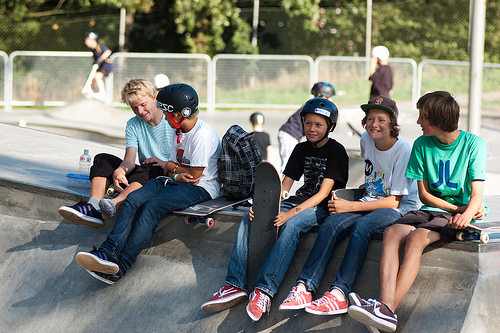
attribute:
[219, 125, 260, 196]
book bag — plaid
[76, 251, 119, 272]
tinnis shoe — black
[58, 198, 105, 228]
tinnis shoe — black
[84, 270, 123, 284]
tinnis shoe — black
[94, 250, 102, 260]
stripe — blue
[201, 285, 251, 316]
tinnis shoe — red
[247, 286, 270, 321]
tinnis shoe — red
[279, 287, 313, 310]
tinnis shoe — red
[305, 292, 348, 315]
tinnis shoe — red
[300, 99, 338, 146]
helmet — black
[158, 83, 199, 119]
helmet — black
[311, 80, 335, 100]
helmet — black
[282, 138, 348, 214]
shirt — black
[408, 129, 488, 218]
shirt — green